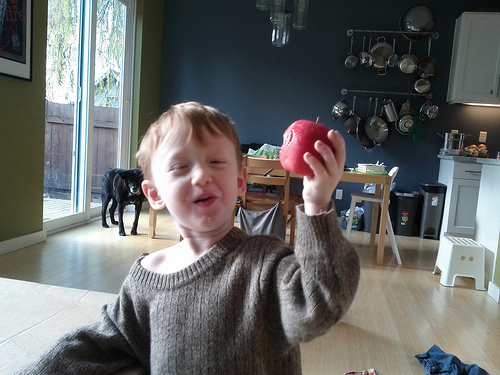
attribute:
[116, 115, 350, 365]
boy — little, holding, wearing, cute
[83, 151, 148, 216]
dog — black, standing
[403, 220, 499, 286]
stool — white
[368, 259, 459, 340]
floor — wood, hardwood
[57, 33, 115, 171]
window — glass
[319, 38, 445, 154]
pans — hanging, grouped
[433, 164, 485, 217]
cabinet — white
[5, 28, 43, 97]
picture — framed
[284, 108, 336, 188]
apple — red, held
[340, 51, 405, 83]
pots — silver, hanging, stainless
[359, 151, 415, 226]
table — wood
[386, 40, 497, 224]
ktichen — white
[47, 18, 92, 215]
doors — sliding, glass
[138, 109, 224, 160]
hair — blonde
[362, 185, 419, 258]
chair — white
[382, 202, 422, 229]
box — plastic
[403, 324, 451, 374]
jeans — thrown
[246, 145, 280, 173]
fruits — placed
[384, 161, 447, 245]
boxes — placed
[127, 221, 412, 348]
sweater — gray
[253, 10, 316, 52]
lamp — hanging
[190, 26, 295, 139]
blue — navy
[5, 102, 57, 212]
wall — green